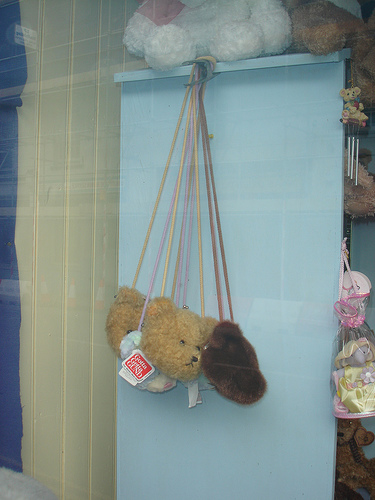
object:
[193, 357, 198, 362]
nose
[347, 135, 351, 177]
chime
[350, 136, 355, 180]
chime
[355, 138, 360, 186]
chime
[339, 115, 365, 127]
stick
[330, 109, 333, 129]
ground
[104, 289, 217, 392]
purse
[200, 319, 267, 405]
head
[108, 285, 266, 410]
stuffed animal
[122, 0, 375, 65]
animals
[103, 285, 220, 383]
teddy bear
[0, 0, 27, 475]
curtain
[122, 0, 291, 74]
teddy bear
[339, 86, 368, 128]
bear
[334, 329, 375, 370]
hat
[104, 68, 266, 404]
purses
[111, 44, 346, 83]
shelf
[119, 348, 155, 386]
tag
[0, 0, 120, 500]
wall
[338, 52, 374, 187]
windchime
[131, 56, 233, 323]
rope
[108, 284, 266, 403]
stuffed animals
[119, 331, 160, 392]
purse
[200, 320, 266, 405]
purse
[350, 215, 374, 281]
wall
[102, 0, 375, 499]
shelf unit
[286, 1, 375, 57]
teddy bear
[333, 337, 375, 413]
animal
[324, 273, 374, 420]
bag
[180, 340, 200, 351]
eyes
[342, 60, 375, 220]
animals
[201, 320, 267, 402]
bear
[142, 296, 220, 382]
bear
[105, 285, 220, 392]
animal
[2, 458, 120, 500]
ground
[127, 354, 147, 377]
words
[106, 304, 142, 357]
legs